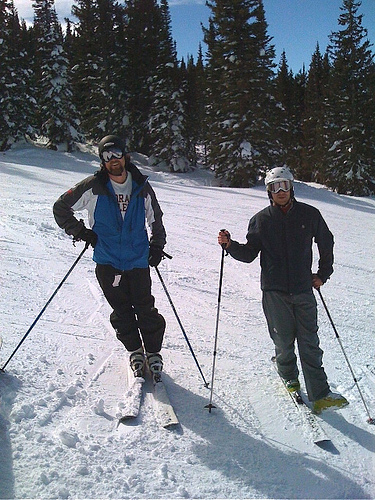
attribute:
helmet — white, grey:
[255, 154, 292, 191]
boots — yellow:
[274, 365, 349, 416]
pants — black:
[82, 271, 164, 370]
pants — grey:
[244, 294, 340, 399]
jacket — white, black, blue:
[69, 168, 166, 278]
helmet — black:
[93, 125, 122, 155]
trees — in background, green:
[11, 25, 372, 175]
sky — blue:
[267, 1, 354, 64]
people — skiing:
[29, 123, 369, 451]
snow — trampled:
[173, 194, 212, 249]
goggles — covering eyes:
[251, 173, 303, 194]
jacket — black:
[211, 209, 343, 300]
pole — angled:
[0, 243, 103, 362]